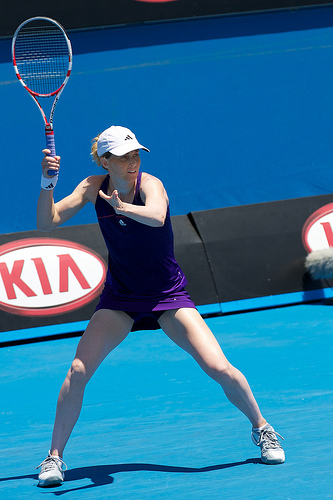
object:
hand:
[40, 148, 61, 178]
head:
[89, 125, 140, 184]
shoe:
[250, 423, 286, 465]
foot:
[250, 418, 285, 466]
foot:
[35, 451, 66, 490]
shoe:
[33, 449, 67, 487]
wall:
[145, 58, 301, 163]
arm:
[36, 186, 90, 231]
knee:
[211, 360, 233, 387]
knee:
[66, 356, 88, 386]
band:
[40, 173, 58, 191]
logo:
[45, 183, 54, 190]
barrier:
[0, 193, 333, 334]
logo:
[0, 235, 108, 320]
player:
[35, 124, 285, 489]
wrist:
[41, 178, 53, 194]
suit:
[90, 171, 198, 333]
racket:
[10, 15, 73, 177]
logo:
[124, 134, 133, 141]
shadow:
[1, 457, 264, 497]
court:
[261, 310, 332, 403]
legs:
[52, 298, 257, 448]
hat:
[96, 125, 150, 159]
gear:
[94, 170, 187, 298]